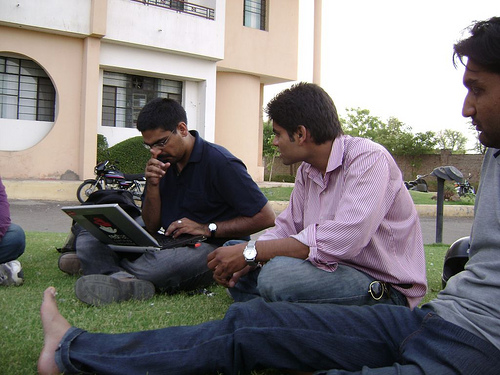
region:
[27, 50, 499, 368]
a group of men sit in the grass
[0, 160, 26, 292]
a portion of one more person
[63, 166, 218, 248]
the man has a laptop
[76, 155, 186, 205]
a motor bike is in the background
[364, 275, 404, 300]
the man has sunglasses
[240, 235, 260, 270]
the man wears a wrist watch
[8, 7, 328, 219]
a building is behind the people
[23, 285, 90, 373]
this man is not wearing a shoe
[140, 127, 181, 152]
the man wears glasses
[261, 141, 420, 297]
the man wears a button down collard shirt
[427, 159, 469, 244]
black solar powered light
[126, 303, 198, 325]
green grass covering ground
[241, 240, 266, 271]
silver metal wristwatch on man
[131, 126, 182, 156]
man wearing silver eye glasses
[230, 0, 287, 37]
window on side of building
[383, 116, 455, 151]
trees covered in green leaves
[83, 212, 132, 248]
sticker on laptop cover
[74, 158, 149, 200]
purple motorcycle parked in front of building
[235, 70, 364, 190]
man with short black hair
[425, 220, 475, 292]
motorcycle helmet laying on grass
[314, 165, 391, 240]
his shirt is pink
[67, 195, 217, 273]
he is using a laptop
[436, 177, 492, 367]
his shirt is gray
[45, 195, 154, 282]
the laptop is black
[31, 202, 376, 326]
sitting on the grass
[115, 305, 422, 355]
his pants are blue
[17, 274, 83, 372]
he is bare foot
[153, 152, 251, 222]
shirt is dark blue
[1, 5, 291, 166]
sitting outside a building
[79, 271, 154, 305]
his souls are black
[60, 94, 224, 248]
A man in blue looks at his laptop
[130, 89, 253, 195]
A man in blue itches his nose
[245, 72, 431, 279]
A man in a pink shirt and watch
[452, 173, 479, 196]
A motorcycle in the background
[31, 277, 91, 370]
A foot with no shoe on it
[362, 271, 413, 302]
Sunglasses in a pocket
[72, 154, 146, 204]
A purple and red motorcycle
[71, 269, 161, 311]
A shoe in the grass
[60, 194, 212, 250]
Somebody typing on a laptop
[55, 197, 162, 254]
A laptop screen with a sticker on the back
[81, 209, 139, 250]
sticker on top of laptop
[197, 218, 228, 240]
black wristwatch on man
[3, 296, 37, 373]
ground covered in green grass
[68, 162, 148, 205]
motorcycle parked in front of building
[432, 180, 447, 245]
black metal pole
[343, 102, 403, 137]
trees with green leaves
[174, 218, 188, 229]
metal ringer on fingers of man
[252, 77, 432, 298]
man in pink shirt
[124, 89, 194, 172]
black haired man in eye glasses